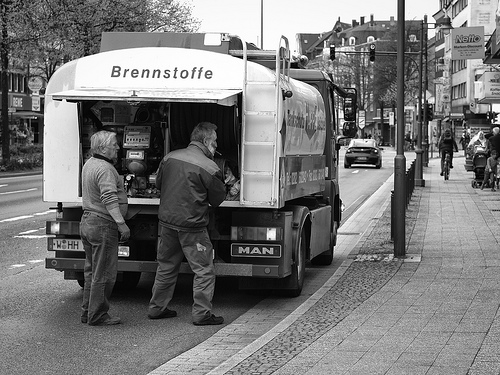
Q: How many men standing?
A: Two.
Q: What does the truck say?
A: Brennstoffe.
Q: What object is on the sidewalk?
A: Poles.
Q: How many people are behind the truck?
A: Two.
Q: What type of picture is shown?
A: Black and white.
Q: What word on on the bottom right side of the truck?
A: The word MAN.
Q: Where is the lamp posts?
A: Sidewalk.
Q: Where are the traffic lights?
A: Over the road.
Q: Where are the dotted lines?
A: Road.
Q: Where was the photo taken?
A: Street.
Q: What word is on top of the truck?
A: Brennstoffe.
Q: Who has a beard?
A: Man wearing jacket.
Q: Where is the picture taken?
A: On a road.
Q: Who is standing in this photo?
A: Two men.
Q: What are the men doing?
A: Getting supplies out of a truck.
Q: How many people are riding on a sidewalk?
A: One.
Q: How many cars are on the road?
A: One.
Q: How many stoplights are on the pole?
A: Two.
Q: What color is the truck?
A: White.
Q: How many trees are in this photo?
A: Two.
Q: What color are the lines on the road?
A: White.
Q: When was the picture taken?
A: Daytime.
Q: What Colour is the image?
A: Black and white.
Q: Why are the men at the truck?
A: The men are unloading it.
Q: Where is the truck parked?
A: On the street.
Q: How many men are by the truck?
A: Two.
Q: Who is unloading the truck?
A: Two men.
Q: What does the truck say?
A: Brennstoffe.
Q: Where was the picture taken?
A: A city.